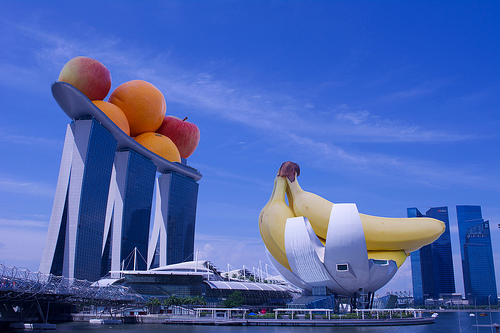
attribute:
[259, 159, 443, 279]
banana bunch — huge, bright yellow, large, yellow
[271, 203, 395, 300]
building — tall, steel, white, tulip shaped, short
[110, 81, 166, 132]
orange — big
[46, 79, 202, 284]
building — tall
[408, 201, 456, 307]
building — tall, in background, high rise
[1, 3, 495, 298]
sky — blue, peaceful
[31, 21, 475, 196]
cloud — soft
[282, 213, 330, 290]
roof top — white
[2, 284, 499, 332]
water — clear, calm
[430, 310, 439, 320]
boat — white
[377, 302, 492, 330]
marina — empty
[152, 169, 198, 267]
building — shiny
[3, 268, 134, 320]
bridge — coil like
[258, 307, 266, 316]
structure — small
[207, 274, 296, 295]
arch — rectangular, white